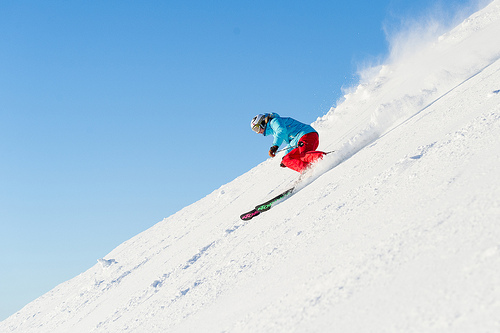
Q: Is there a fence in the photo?
A: No, there are no fences.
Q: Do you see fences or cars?
A: No, there are no fences or cars.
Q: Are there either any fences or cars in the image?
A: No, there are no fences or cars.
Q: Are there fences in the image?
A: No, there are no fences.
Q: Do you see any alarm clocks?
A: No, there are no alarm clocks.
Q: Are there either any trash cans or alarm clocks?
A: No, there are no alarm clocks or trash cans.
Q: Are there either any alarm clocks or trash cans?
A: No, there are no alarm clocks or trash cans.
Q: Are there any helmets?
A: Yes, there is a helmet.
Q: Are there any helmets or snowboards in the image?
A: Yes, there is a helmet.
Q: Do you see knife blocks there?
A: No, there are no knife blocks.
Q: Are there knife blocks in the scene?
A: No, there are no knife blocks.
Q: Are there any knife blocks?
A: No, there are no knife blocks.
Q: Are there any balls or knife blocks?
A: No, there are no knife blocks or balls.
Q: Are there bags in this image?
A: No, there are no bags.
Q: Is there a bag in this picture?
A: No, there are no bags.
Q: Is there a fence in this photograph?
A: No, there are no fences.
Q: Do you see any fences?
A: No, there are no fences.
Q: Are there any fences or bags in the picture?
A: No, there are no fences or bags.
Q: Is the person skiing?
A: Yes, the person is skiing.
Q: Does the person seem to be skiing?
A: Yes, the person is skiing.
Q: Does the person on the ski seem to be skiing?
A: Yes, the person is skiing.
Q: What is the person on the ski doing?
A: The person is skiing.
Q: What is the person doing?
A: The person is skiing.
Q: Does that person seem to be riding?
A: No, the person is skiing.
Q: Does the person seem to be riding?
A: No, the person is skiing.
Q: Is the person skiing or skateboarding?
A: The person is skiing.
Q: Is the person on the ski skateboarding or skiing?
A: The person is skiing.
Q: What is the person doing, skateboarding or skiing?
A: The person is skiing.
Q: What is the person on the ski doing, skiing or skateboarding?
A: The person is skiing.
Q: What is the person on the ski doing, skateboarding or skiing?
A: The person is skiing.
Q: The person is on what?
A: The person is on the ski.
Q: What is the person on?
A: The person is on the ski.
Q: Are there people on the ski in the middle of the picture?
A: Yes, there is a person on the ski.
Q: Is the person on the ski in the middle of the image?
A: Yes, the person is on the ski.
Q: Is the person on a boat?
A: No, the person is on the ski.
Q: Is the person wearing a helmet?
A: Yes, the person is wearing a helmet.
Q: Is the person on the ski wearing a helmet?
A: Yes, the person is wearing a helmet.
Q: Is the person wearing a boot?
A: No, the person is wearing a helmet.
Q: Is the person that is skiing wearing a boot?
A: No, the person is wearing a helmet.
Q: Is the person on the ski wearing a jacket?
A: Yes, the person is wearing a jacket.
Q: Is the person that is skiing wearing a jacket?
A: Yes, the person is wearing a jacket.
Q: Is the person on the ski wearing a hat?
A: No, the person is wearing a jacket.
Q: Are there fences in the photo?
A: No, there are no fences.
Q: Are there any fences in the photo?
A: No, there are no fences.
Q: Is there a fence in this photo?
A: No, there are no fences.